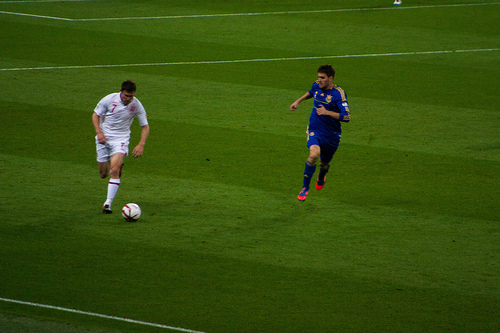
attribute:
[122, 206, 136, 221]
stripes — red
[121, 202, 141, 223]
ball — white, red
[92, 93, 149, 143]
jersey — white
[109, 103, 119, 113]
number — red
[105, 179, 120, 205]
sock — white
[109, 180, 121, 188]
stripe — red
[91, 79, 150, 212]
man — kicking, playing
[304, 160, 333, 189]
socks — blue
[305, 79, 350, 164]
uniform — blue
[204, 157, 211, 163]
patch — black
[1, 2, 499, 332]
field — here, green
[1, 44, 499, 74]
line — here, white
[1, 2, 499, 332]
ground — here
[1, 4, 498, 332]
grass — here, green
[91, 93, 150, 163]
uniform — white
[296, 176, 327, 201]
shoes — red, blue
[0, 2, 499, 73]
lines — yellow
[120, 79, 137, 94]
hair — brown, short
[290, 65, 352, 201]
man — running, playing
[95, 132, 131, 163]
shorts — white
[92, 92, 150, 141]
top — white